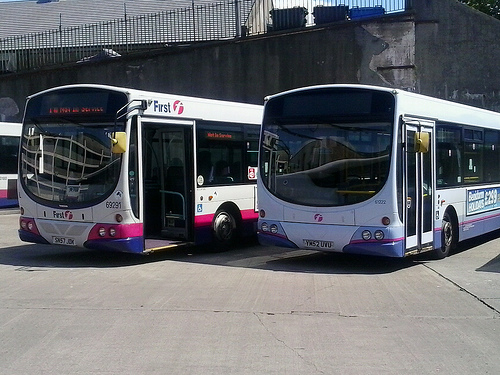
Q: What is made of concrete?
A: The ground.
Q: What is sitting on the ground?
A: The bus.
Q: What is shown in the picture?
A: The door to the bus.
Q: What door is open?
A: The bus.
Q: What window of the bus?
A: The front.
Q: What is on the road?
A: Two buses.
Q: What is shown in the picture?
A: Red and white bus.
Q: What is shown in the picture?
A: Blue and white bus.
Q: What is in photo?
A: Buses.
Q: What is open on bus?
A: Main door.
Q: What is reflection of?
A: Building.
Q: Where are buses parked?
A: Concrete ground.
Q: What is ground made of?
A: Concrete.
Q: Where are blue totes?
A: Above the buses.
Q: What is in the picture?
A: Buses.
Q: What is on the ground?
A: Concert.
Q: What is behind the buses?
A: Wall.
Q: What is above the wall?
A: Gate.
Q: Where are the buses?
A: Parking lot.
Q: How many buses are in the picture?
A: Three.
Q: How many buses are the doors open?
A: One.